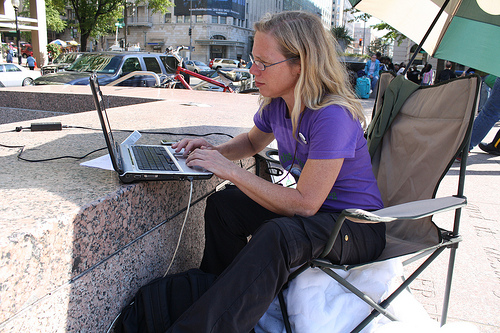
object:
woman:
[156, 8, 392, 332]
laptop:
[88, 73, 218, 184]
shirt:
[250, 95, 384, 214]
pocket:
[304, 215, 356, 268]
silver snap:
[344, 233, 350, 242]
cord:
[105, 178, 198, 332]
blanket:
[254, 258, 479, 332]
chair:
[256, 74, 484, 333]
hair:
[252, 8, 370, 144]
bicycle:
[155, 44, 261, 96]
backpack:
[113, 266, 205, 331]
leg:
[179, 211, 390, 332]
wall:
[0, 84, 298, 332]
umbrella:
[344, 0, 500, 81]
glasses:
[248, 54, 297, 70]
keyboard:
[130, 145, 180, 172]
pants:
[157, 183, 388, 331]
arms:
[228, 120, 351, 219]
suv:
[26, 50, 191, 89]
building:
[0, 0, 334, 70]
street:
[0, 52, 500, 333]